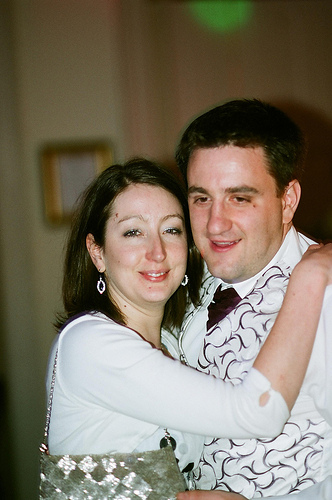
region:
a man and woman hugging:
[83, 97, 314, 486]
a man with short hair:
[177, 81, 313, 264]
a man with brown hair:
[175, 80, 308, 237]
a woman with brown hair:
[66, 147, 190, 331]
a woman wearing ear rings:
[82, 165, 191, 304]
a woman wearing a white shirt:
[58, 171, 188, 411]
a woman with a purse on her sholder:
[46, 147, 190, 496]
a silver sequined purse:
[4, 433, 202, 497]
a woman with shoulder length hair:
[51, 153, 198, 348]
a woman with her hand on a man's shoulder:
[64, 122, 324, 451]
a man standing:
[167, 93, 330, 492]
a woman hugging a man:
[41, 152, 331, 498]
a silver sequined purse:
[39, 315, 195, 498]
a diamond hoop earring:
[94, 273, 104, 293]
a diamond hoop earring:
[181, 273, 187, 284]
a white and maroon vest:
[167, 232, 315, 493]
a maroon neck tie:
[206, 282, 238, 328]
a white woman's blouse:
[39, 310, 289, 474]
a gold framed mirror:
[36, 130, 114, 228]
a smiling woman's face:
[74, 161, 201, 331]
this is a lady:
[67, 191, 181, 402]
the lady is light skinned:
[117, 247, 131, 275]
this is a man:
[194, 123, 274, 280]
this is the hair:
[73, 198, 89, 226]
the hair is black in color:
[75, 203, 101, 221]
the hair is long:
[61, 252, 88, 294]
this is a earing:
[92, 279, 111, 293]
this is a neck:
[212, 293, 226, 306]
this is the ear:
[283, 177, 304, 219]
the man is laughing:
[195, 236, 243, 251]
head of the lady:
[85, 164, 199, 310]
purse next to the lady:
[41, 418, 181, 496]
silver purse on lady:
[40, 410, 148, 499]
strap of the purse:
[32, 341, 89, 447]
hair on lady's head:
[78, 188, 108, 222]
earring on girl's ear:
[88, 269, 115, 300]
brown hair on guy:
[216, 105, 285, 141]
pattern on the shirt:
[244, 439, 299, 485]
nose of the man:
[202, 195, 229, 240]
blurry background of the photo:
[21, 95, 91, 177]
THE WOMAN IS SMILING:
[133, 267, 177, 286]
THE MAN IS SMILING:
[203, 227, 254, 251]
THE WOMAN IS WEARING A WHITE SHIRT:
[24, 308, 291, 498]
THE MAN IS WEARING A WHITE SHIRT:
[162, 230, 328, 498]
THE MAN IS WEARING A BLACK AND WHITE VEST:
[158, 242, 331, 499]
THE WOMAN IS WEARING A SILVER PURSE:
[26, 313, 197, 498]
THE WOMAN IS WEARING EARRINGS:
[92, 260, 209, 308]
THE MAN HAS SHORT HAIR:
[163, 87, 310, 213]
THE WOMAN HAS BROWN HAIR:
[41, 152, 206, 354]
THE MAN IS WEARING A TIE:
[204, 285, 244, 331]